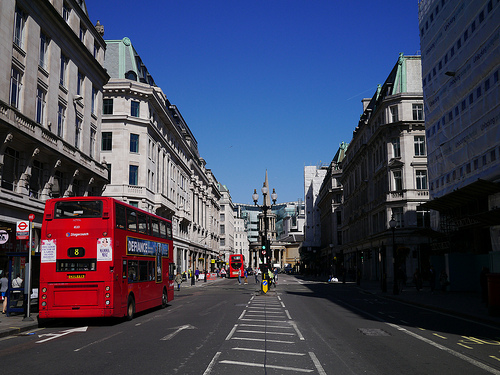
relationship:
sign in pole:
[16, 221, 27, 234] [23, 213, 33, 324]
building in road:
[414, 0, 499, 326] [4, 261, 498, 373]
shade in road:
[288, 254, 498, 343] [4, 261, 498, 373]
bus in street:
[38, 195, 174, 321] [0, 272, 496, 372]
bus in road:
[38, 195, 174, 321] [34, 259, 389, 372]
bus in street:
[228, 250, 246, 278] [0, 272, 496, 372]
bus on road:
[38, 195, 174, 321] [184, 283, 421, 365]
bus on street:
[38, 195, 174, 321] [0, 272, 496, 372]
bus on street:
[228, 252, 245, 278] [0, 272, 496, 372]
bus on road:
[31, 191, 184, 323] [198, 283, 371, 348]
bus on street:
[38, 195, 174, 321] [227, 285, 296, 330]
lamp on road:
[251, 165, 278, 263] [4, 261, 498, 373]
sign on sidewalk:
[216, 265, 226, 279] [170, 273, 226, 288]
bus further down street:
[228, 252, 245, 278] [4, 257, 499, 374]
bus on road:
[38, 195, 174, 321] [4, 270, 497, 371]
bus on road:
[228, 252, 245, 278] [4, 270, 497, 371]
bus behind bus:
[38, 195, 174, 321] [25, 197, 192, 335]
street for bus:
[203, 282, 345, 373] [38, 195, 174, 321]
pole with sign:
[27, 214, 37, 324] [16, 221, 27, 234]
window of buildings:
[128, 134, 140, 154] [100, 42, 240, 277]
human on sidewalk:
[0, 271, 50, 339] [4, 260, 222, 333]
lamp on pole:
[251, 165, 278, 263] [259, 189, 270, 266]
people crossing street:
[228, 262, 283, 289] [88, 245, 412, 340]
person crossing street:
[174, 270, 182, 290] [0, 272, 496, 372]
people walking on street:
[186, 253, 227, 284] [198, 282, 310, 370]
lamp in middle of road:
[257, 178, 273, 289] [4, 261, 498, 373]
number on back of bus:
[72, 246, 80, 257] [224, 256, 252, 280]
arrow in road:
[155, 319, 200, 340] [4, 261, 498, 373]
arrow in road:
[34, 324, 95, 342] [4, 261, 498, 373]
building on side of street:
[81, 29, 223, 296] [0, 272, 496, 372]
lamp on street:
[251, 165, 278, 263] [203, 250, 415, 373]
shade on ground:
[288, 254, 498, 343] [0, 264, 499, 374]